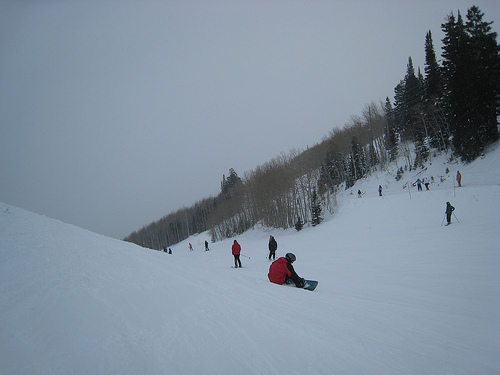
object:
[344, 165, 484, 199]
path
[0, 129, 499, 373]
snow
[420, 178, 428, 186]
jacket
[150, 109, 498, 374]
ground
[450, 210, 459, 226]
poles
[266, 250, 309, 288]
man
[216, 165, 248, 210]
tree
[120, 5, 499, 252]
forest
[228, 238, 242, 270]
person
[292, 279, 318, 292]
snowboad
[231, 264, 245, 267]
skiis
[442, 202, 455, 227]
person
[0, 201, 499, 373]
mountain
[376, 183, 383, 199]
hiker in distance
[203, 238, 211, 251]
skier in blue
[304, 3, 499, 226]
living fir trees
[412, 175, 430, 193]
two skiers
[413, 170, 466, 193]
three people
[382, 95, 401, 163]
green pine trees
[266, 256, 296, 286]
snowboarder jacket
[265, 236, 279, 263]
skiers standing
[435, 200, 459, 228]
holding ski poles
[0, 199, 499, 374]
ski slope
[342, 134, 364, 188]
green trees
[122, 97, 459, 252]
leafless trees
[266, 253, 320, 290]
sitting down on the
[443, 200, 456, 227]
standing in the snow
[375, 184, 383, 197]
standing in the snow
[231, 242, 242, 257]
in a red jacket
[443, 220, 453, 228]
some skis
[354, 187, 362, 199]
person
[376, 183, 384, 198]
person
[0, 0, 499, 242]
sky is cloudy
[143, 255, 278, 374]
snow has tracks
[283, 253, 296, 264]
helmet on